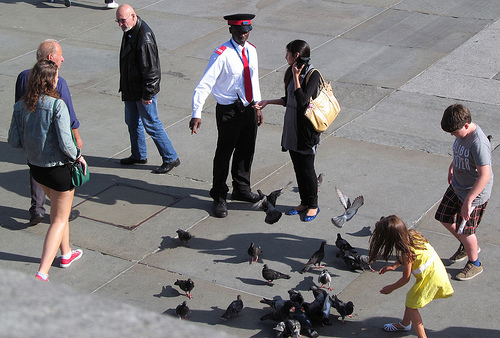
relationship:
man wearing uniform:
[183, 8, 270, 223] [186, 40, 267, 203]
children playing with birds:
[362, 97, 499, 337] [160, 181, 377, 337]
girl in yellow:
[362, 206, 460, 337] [397, 235, 459, 309]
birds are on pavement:
[160, 181, 377, 337] [9, 167, 373, 322]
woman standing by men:
[256, 35, 344, 231] [183, 8, 270, 223]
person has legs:
[109, 1, 185, 178] [116, 95, 187, 179]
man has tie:
[183, 8, 270, 223] [237, 47, 257, 106]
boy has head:
[427, 98, 496, 283] [429, 97, 490, 152]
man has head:
[183, 8, 270, 223] [214, 8, 266, 57]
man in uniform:
[183, 8, 270, 223] [186, 40, 267, 203]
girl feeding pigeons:
[362, 206, 460, 337] [160, 181, 377, 337]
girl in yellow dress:
[362, 206, 460, 337] [397, 235, 459, 309]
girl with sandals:
[362, 206, 460, 337] [381, 319, 419, 336]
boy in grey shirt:
[427, 98, 496, 283] [443, 129, 499, 207]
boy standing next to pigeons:
[427, 98, 496, 283] [160, 181, 377, 337]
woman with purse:
[1, 55, 96, 292] [68, 161, 92, 186]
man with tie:
[183, 8, 270, 223] [237, 47, 257, 106]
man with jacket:
[109, 1, 185, 178] [111, 25, 168, 99]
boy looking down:
[427, 98, 496, 283] [413, 199, 442, 238]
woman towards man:
[256, 35, 344, 231] [183, 8, 270, 223]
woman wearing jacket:
[1, 55, 96, 292] [3, 93, 82, 170]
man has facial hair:
[109, 1, 185, 178] [117, 21, 135, 33]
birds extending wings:
[326, 181, 366, 231] [333, 180, 369, 213]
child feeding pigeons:
[362, 206, 460, 337] [160, 181, 377, 337]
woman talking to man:
[256, 35, 344, 231] [183, 8, 270, 223]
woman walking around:
[1, 55, 96, 292] [5, 2, 185, 290]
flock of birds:
[160, 181, 377, 337] [179, 255, 355, 322]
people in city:
[4, 1, 495, 330] [27, 11, 494, 322]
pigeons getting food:
[330, 291, 361, 323] [345, 284, 395, 335]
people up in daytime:
[4, 1, 495, 330] [15, 13, 488, 334]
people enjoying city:
[4, 1, 495, 330] [27, 11, 494, 322]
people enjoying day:
[4, 1, 495, 330] [14, 13, 486, 333]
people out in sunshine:
[4, 1, 495, 330] [15, 14, 391, 330]